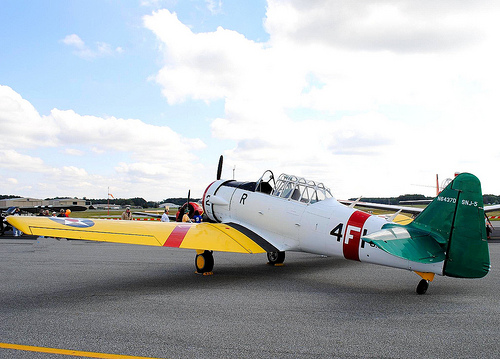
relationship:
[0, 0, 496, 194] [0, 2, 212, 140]
cloud in blue sky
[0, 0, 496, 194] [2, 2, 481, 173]
cloud in sky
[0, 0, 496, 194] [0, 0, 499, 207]
cloud in sky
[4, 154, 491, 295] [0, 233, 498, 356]
airplane on ground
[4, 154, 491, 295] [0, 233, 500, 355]
airplane on runway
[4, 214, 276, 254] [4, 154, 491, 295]
wing has airplane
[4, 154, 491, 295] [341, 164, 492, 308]
airplane has green tail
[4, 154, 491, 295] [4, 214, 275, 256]
airplane has wing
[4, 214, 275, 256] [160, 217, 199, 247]
wing has stripe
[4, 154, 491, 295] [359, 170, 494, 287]
airplane has tail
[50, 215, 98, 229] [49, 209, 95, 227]
circle inside circle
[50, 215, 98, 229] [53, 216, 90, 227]
circle has star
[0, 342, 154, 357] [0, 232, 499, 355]
line painted on tarmac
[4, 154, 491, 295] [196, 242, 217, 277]
airplane has tire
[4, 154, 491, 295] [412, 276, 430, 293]
airplane has tire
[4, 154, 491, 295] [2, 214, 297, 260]
airplane has wings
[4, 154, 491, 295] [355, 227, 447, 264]
airplane has wings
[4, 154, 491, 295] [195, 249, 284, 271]
airplane has wheels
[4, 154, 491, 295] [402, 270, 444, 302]
airplane has wheels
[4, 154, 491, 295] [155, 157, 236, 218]
airplane has motor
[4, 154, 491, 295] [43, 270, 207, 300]
airplane has shadow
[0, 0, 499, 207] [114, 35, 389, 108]
sky full of clouds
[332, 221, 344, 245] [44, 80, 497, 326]
number on plane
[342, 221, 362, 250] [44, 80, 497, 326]
letter on plane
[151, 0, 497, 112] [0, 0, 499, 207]
cloud in sky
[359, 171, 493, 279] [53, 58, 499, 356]
green tail on plane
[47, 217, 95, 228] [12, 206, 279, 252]
circle on wing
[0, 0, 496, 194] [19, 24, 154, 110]
cloud in blue sky